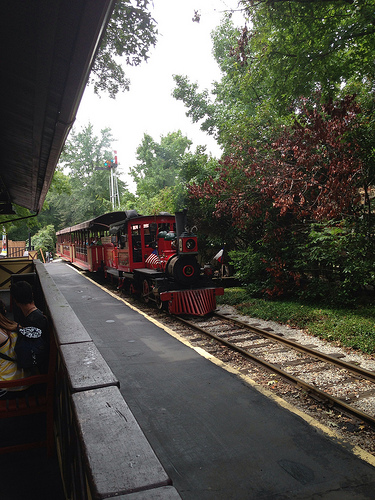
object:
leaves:
[186, 92, 366, 231]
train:
[54, 209, 226, 317]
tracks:
[166, 307, 367, 423]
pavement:
[41, 259, 367, 493]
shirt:
[1, 330, 19, 381]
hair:
[10, 281, 34, 304]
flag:
[144, 248, 158, 264]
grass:
[217, 283, 373, 354]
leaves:
[267, 379, 367, 434]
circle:
[182, 264, 196, 279]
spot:
[106, 318, 114, 325]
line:
[63, 259, 370, 459]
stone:
[72, 384, 170, 492]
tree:
[186, 87, 372, 295]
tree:
[171, 6, 370, 177]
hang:
[5, 1, 111, 227]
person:
[45, 246, 52, 262]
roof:
[110, 209, 174, 230]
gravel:
[208, 322, 369, 411]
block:
[59, 339, 120, 445]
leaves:
[219, 5, 366, 111]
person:
[1, 313, 29, 395]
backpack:
[15, 326, 44, 370]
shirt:
[21, 309, 53, 377]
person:
[11, 282, 53, 375]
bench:
[1, 327, 60, 467]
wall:
[29, 259, 177, 498]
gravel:
[256, 373, 372, 441]